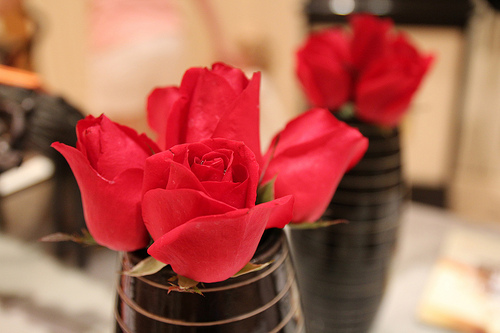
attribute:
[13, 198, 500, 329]
table — shiny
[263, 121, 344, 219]
flower — red, red color, blooming, rose, silghtly opened, unopened, opening, blurry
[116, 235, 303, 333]
vase — brown, black, shiny, short, tall, chocolate brown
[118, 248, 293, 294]
lines — thin, light brown, white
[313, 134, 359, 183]
petal — red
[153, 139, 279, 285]
flower — rose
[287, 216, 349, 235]
leaf — green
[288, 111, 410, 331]
vase — black, brown